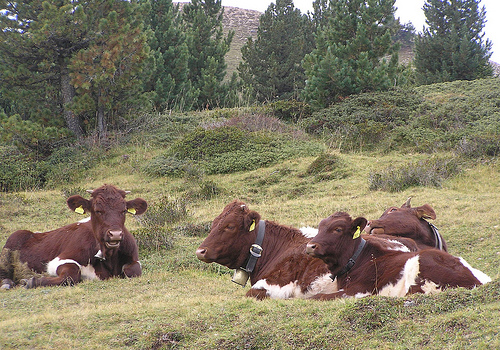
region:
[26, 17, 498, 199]
Picture taken during the day.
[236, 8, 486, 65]
The sky is light grey.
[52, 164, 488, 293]
Four cows laying down.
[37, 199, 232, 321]
Cow is facing the camera.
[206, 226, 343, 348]
Cow is brown and white.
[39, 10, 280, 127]
Trees are full of leaves.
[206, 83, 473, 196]
Small hills behind the cows.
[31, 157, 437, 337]
The cows are are not standing.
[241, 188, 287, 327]
Cow is wearing a collar.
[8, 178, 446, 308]
the cows are four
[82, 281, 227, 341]
the grass is green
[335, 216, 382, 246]
the ear has tags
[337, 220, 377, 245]
the tags are yellow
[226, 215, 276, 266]
the collar is black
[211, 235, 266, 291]
the bell is golden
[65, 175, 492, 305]
the cows are relaxing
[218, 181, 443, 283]
the cows are brown and white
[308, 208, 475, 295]
the cow has no horns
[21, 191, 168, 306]
the cow has its mouth open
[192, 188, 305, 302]
brown white cow with gold bell hanging from neck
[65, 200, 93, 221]
yellow tag in ear of cow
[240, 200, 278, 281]
black strap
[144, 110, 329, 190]
green grassy hill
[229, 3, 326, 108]
green pine tree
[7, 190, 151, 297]
brown white cow lying on grassy ground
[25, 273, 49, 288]
black cow hoof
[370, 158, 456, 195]
brush the color of straw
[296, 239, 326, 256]
large nostril of cow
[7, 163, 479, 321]
group of cow lying on the green hill side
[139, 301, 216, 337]
part of some grass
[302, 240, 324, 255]
nose of a cow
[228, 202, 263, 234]
left ear of a cow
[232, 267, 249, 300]
part of a bell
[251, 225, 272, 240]
part of a belt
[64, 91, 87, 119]
stem of a tree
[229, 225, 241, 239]
left eye of the cow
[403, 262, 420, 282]
white hair on the cow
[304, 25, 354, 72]
part of some tree branches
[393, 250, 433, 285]
stomach of a cow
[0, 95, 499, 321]
some cows out resting.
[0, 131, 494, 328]
some big cows out resting.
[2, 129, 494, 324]
group of cows out resting.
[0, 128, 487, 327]
multiple cows out resting.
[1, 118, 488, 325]
some cows sitting on ground.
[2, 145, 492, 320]
large cows sitting on ground.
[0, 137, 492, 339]
adult cows sitting on ground.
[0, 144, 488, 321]
brown and white cows sitting on ground.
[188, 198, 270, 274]
large head of a cow.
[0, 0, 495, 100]
several green trees in view.